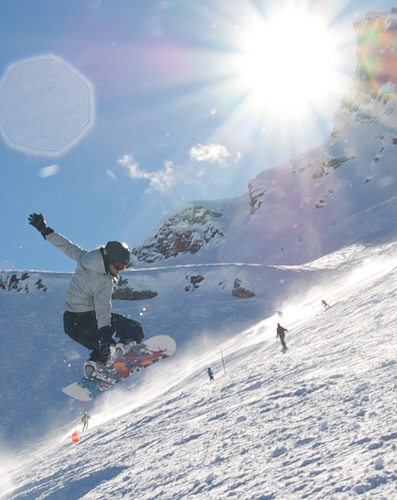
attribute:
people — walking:
[271, 309, 286, 358]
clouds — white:
[119, 141, 236, 194]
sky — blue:
[2, 3, 387, 242]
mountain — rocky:
[126, 126, 375, 315]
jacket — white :
[45, 231, 115, 327]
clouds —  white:
[188, 143, 229, 165]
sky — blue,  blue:
[2, 2, 381, 271]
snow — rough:
[4, 254, 391, 499]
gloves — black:
[26, 209, 116, 356]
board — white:
[61, 333, 177, 401]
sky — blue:
[34, 13, 153, 98]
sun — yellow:
[212, 5, 358, 146]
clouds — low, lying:
[97, 95, 213, 182]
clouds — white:
[50, 64, 219, 215]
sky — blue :
[14, 10, 396, 298]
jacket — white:
[40, 229, 117, 330]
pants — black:
[47, 306, 163, 363]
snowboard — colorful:
[61, 335, 181, 404]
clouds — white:
[107, 149, 216, 188]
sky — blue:
[3, 10, 242, 215]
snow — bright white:
[310, 314, 388, 370]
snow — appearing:
[1, 85, 392, 498]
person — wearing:
[29, 212, 144, 376]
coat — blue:
[47, 231, 116, 327]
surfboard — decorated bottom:
[61, 334, 177, 402]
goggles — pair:
[108, 258, 131, 273]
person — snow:
[114, 319, 155, 363]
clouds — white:
[4, 57, 237, 215]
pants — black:
[62, 311, 145, 357]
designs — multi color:
[73, 343, 167, 397]